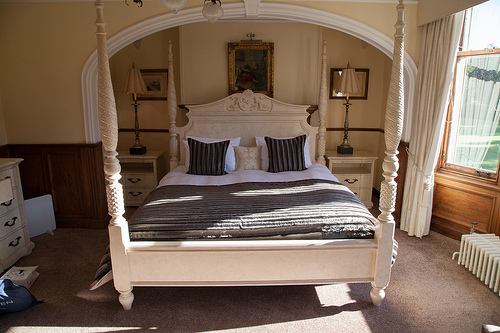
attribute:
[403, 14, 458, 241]
drapes — white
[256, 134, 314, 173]
pillow — white, black, decorative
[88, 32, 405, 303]
bed — white 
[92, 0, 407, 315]
bed — large, king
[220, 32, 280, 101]
framed picture — gold, antique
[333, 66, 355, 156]
tall lamps — elegant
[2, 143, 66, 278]
dresser — white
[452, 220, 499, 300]
heater — air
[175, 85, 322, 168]
headboard — wooden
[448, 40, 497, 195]
windows — large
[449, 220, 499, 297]
radiator — white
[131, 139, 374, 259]
blanket — gray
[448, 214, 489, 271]
radiator — white 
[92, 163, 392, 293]
comforter — king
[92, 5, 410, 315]
bed frame — cream colored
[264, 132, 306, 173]
pillow — black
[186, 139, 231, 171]
pillow — striped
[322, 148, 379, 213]
end table — white 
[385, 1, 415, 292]
posts — four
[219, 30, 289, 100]
picture — elegant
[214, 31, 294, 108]
frame — gold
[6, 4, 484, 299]
bedroom — symmetry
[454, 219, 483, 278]
pipe — white